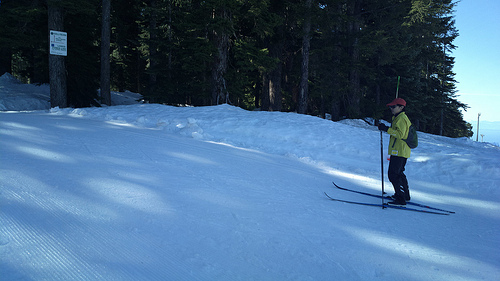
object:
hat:
[386, 98, 406, 107]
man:
[378, 98, 418, 207]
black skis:
[323, 181, 456, 215]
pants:
[388, 155, 411, 205]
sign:
[49, 30, 67, 57]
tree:
[47, 0, 70, 106]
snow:
[0, 73, 498, 278]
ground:
[2, 73, 499, 277]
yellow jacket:
[387, 111, 413, 158]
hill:
[0, 76, 500, 281]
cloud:
[463, 57, 494, 91]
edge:
[92, 112, 174, 137]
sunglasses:
[389, 105, 404, 108]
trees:
[225, 5, 453, 115]